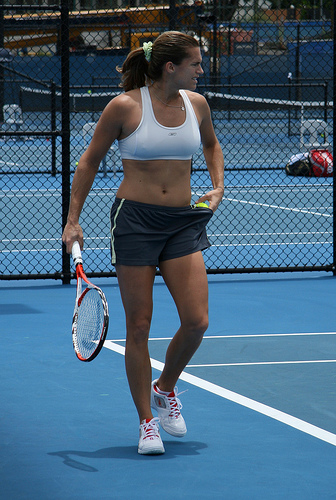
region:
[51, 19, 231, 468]
tennis player in a tennis court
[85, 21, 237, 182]
tennis player combs in a pony tail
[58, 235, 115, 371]
a racket color white, red and black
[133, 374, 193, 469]
white tennis shoe with pins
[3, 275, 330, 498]
tennis court is blue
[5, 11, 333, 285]
a fence color black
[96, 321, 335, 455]
white lines on tennis court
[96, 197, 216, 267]
blue short with white stripes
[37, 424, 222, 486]
shadow cast on the ground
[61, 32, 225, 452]
a woman playing tennis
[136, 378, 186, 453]
a white and red sneakers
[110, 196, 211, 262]
black shorts with a white line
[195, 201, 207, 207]
a yellow tennis ball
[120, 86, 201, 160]
a woman wearing a sport bra top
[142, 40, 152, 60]
a green scrunchie in woman's hair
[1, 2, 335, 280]
a black fence on a tennis court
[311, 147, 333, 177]
a red and white bag on the floor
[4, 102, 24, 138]
a chair on a tennis floor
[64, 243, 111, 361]
red and white tennis racket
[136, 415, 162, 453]
red and white tennis shoes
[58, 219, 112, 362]
hand holding tennis racket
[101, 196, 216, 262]
grey shorts with stripe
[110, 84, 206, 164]
white sport bra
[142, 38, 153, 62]
white pony tail holder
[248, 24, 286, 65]
black chain link fence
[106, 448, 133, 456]
shadow on tennis court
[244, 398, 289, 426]
white line on tennis court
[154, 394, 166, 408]
emblem on tennis shoe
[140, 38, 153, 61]
green bow in womans hair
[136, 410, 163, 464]
woman wearing white sneakers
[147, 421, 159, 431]
white shoestrings in sneakers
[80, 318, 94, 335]
inside of tennis racket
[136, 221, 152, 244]
woman wearing grey shorts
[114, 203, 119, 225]
white stripe on shorts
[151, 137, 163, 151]
woman wearing white halter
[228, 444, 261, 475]
blue paint on court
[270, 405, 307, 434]
thick white line on court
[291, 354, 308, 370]
thin white line on court